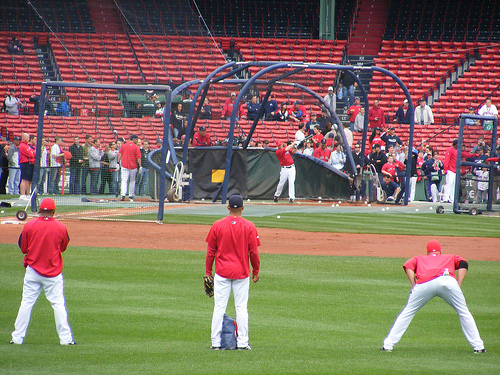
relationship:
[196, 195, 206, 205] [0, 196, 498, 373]
baseballs on field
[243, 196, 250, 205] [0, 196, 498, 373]
baseballs on field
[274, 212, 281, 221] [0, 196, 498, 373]
baseballs on field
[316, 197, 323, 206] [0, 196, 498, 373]
baseballs on field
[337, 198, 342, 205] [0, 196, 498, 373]
baseballs on field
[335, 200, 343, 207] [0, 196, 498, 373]
baseballs on field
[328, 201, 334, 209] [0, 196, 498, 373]
baseballs on field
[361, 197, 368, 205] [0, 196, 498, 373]
baseballs on field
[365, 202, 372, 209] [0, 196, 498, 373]
baseballs on field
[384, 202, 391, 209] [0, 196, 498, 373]
baseballs on field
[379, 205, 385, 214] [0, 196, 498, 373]
baseballs on field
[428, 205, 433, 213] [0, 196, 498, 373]
baseballs on field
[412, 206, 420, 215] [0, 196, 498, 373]
baseballs on field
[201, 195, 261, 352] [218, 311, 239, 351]
man has bag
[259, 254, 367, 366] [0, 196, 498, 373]
grass on field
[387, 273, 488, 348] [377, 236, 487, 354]
pants on man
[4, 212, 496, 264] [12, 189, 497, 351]
dirt on field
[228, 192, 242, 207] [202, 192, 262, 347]
hat on player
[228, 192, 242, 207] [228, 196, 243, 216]
hat on head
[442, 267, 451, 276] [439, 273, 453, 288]
bottle in pocket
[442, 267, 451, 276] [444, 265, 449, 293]
bottle of water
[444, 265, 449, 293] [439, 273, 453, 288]
water in pocket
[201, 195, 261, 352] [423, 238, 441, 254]
man wearing hat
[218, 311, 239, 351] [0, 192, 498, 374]
bag on field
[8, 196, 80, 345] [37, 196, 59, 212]
man wearing hat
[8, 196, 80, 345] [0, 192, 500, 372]
man on baseball field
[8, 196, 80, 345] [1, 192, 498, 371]
man on basebal field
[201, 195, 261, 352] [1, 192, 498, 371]
man on basebal field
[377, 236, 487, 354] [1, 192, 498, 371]
man on basebal field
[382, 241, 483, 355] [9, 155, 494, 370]
man on baseball field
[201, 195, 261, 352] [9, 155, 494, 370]
man on baseball field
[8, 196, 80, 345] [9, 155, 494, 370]
man on baseball field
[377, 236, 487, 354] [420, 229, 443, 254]
man wearing hat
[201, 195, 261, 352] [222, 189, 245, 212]
man wearing hat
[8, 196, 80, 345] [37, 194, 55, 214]
man wearing hat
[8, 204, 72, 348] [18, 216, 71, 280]
man wearing baseball jersey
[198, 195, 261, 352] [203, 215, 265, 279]
man wearing baseball jersey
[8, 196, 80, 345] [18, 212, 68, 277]
man wearing baseball jersey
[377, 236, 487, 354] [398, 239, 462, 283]
man wearing baseball jersey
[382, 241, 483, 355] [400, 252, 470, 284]
man wearing baseball jersey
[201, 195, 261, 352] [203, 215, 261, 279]
man wearing baseball jersey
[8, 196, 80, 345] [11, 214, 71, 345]
man wearing jersey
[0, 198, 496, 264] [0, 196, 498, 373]
dirt on field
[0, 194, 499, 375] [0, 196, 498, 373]
grass on field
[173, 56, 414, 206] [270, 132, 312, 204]
frame above baseball batter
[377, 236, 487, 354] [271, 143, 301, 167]
man wearing jersey